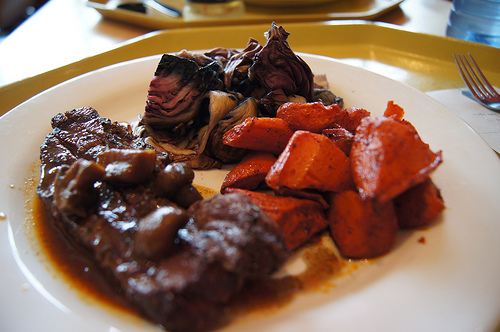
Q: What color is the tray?
A: Yellow.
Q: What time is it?
A: Afternoon.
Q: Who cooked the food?
A: A chef.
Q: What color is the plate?
A: White.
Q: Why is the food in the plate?
A: For eating.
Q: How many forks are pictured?
A: One.